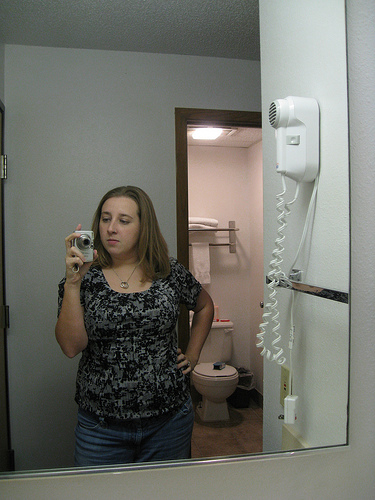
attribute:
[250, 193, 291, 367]
wire — white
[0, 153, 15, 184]
hinge — silver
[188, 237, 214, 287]
hand towel — white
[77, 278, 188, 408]
blouse — printed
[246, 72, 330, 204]
hair dryer — white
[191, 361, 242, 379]
toilet cover — down